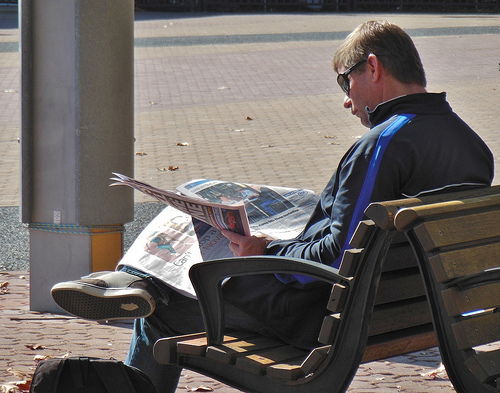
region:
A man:
[230, 105, 425, 342]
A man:
[240, 161, 377, 328]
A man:
[294, 139, 361, 341]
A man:
[270, 230, 359, 388]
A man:
[243, 200, 310, 307]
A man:
[303, 134, 398, 272]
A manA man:
[239, 164, 353, 373]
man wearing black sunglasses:
[329, 57, 379, 99]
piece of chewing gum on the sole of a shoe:
[116, 296, 147, 316]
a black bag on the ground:
[29, 342, 165, 389]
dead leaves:
[133, 129, 196, 178]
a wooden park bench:
[177, 218, 407, 391]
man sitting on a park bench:
[200, 24, 480, 357]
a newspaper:
[108, 169, 313, 280]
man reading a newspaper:
[140, 40, 455, 280]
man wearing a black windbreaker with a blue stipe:
[268, 99, 495, 271]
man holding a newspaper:
[136, 149, 348, 281]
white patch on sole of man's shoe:
[119, 302, 140, 314]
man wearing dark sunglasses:
[335, 62, 364, 94]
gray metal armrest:
[187, 256, 345, 344]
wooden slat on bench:
[414, 207, 498, 250]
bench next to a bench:
[147, 186, 497, 391]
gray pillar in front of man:
[17, 0, 134, 314]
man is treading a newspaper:
[106, 169, 321, 300]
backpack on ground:
[28, 356, 155, 391]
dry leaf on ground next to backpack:
[2, 381, 22, 391]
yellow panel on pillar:
[90, 226, 123, 271]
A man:
[348, 146, 430, 296]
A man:
[334, 24, 489, 341]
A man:
[302, 61, 412, 236]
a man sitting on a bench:
[161, 0, 458, 388]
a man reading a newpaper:
[146, 27, 426, 240]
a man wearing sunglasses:
[313, 30, 400, 130]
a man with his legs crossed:
[75, 38, 427, 326]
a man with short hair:
[306, 14, 436, 105]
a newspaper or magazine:
[117, 163, 311, 305]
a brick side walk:
[158, 72, 308, 172]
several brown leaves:
[155, 102, 301, 177]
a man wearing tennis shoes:
[33, 250, 170, 334]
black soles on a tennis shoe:
[54, 273, 159, 319]